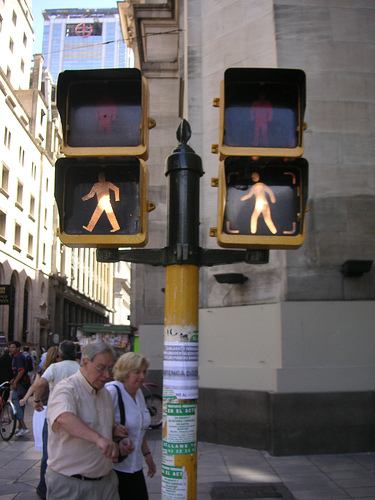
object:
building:
[117, 0, 375, 456]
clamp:
[209, 226, 218, 238]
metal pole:
[158, 120, 204, 498]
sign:
[54, 155, 149, 247]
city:
[0, 1, 374, 498]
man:
[45, 340, 136, 499]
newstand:
[75, 319, 132, 337]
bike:
[0, 380, 17, 442]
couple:
[46, 339, 156, 498]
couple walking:
[44, 341, 158, 499]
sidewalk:
[0, 422, 374, 498]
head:
[81, 342, 119, 389]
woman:
[102, 351, 157, 499]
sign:
[214, 152, 311, 243]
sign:
[217, 66, 306, 148]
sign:
[56, 67, 151, 156]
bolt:
[172, 244, 183, 259]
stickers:
[163, 343, 199, 396]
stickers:
[166, 404, 199, 439]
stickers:
[163, 442, 195, 454]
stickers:
[161, 468, 187, 499]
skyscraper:
[40, 8, 129, 89]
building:
[0, 0, 115, 341]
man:
[7, 343, 32, 439]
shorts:
[9, 386, 29, 420]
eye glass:
[89, 356, 113, 375]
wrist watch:
[142, 450, 152, 457]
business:
[0, 325, 156, 492]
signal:
[216, 153, 310, 251]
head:
[111, 352, 147, 393]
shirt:
[102, 378, 150, 472]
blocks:
[339, 129, 375, 166]